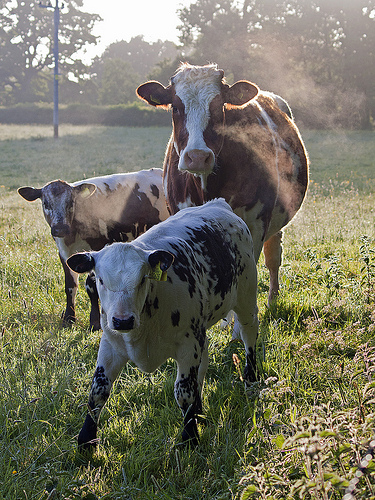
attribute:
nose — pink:
[184, 151, 221, 174]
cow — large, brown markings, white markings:
[133, 67, 309, 245]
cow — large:
[10, 163, 171, 243]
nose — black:
[102, 310, 136, 337]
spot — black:
[169, 308, 181, 328]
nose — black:
[89, 303, 162, 349]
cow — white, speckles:
[85, 200, 288, 359]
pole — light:
[37, 1, 67, 140]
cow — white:
[18, 167, 163, 230]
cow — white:
[136, 63, 313, 213]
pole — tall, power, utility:
[43, 0, 64, 142]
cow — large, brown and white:
[148, 44, 339, 276]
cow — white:
[58, 194, 277, 453]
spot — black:
[173, 236, 248, 304]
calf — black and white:
[63, 196, 260, 446]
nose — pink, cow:
[182, 148, 214, 173]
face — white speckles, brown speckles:
[32, 179, 92, 243]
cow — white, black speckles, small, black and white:
[64, 197, 259, 462]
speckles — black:
[174, 216, 256, 292]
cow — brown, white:
[138, 59, 300, 229]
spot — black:
[191, 351, 199, 361]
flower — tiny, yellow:
[9, 468, 20, 475]